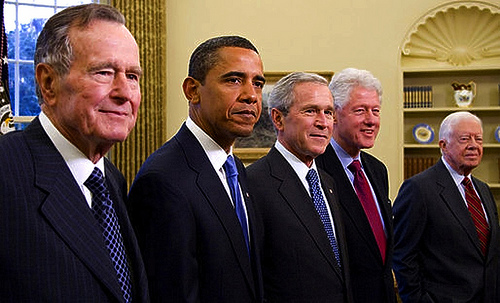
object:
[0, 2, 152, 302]
george bush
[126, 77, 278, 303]
barack obama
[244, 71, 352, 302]
george bush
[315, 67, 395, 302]
bill clinton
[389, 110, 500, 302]
jimmy carter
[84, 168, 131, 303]
tie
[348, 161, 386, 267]
tie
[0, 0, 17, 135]
flag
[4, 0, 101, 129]
window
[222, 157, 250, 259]
tie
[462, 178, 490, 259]
tie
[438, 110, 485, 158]
hair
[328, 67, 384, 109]
hair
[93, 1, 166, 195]
drapes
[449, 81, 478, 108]
pitcher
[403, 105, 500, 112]
shelf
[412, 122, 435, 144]
plate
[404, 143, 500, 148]
shelf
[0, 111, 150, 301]
suit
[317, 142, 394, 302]
suit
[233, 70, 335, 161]
painting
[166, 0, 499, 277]
wall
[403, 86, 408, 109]
books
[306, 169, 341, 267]
tie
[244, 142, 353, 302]
suit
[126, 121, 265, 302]
suit